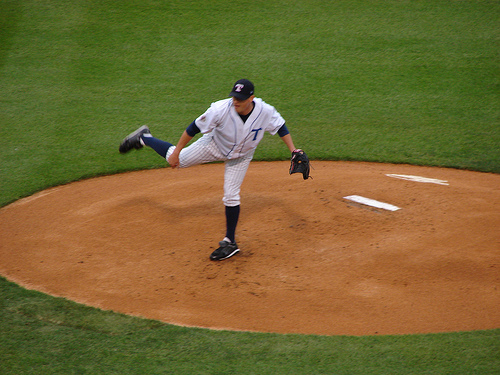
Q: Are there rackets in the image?
A: No, there are no rackets.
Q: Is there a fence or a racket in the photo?
A: No, there are no rackets or fences.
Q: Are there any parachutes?
A: No, there are no parachutes.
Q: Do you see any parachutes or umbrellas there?
A: No, there are no parachutes or umbrellas.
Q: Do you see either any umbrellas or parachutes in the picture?
A: No, there are no parachutes or umbrellas.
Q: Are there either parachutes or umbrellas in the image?
A: No, there are no parachutes or umbrellas.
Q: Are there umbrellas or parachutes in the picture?
A: No, there are no parachutes or umbrellas.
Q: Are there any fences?
A: No, there are no fences.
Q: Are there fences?
A: No, there are no fences.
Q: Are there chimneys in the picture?
A: No, there are no chimneys.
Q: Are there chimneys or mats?
A: No, there are no chimneys or mats.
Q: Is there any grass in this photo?
A: Yes, there is grass.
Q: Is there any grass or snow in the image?
A: Yes, there is grass.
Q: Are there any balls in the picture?
A: No, there are no balls.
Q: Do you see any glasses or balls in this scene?
A: No, there are no balls or glasses.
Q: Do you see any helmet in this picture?
A: No, there are no helmets.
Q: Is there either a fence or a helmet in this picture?
A: No, there are no helmets or fences.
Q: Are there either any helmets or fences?
A: No, there are no helmets or fences.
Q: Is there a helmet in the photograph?
A: No, there are no helmets.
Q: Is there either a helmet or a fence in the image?
A: No, there are no helmets or fences.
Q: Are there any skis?
A: No, there are no skis.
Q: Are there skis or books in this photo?
A: No, there are no skis or books.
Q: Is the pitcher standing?
A: Yes, the pitcher is standing.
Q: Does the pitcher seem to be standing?
A: Yes, the pitcher is standing.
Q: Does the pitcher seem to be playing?
A: Yes, the pitcher is playing.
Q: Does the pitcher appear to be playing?
A: Yes, the pitcher is playing.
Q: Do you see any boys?
A: No, there are no boys.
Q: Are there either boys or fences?
A: No, there are no boys or fences.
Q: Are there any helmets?
A: No, there are no helmets.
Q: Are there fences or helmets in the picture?
A: No, there are no helmets or fences.